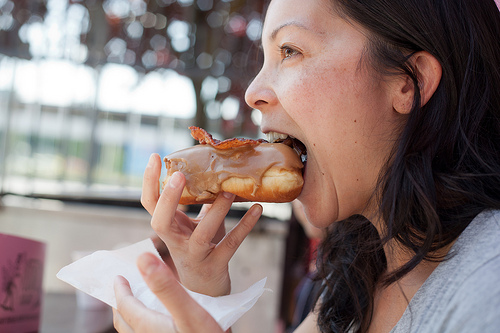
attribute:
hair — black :
[390, 75, 459, 225]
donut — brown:
[156, 106, 347, 286]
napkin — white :
[32, 218, 268, 328]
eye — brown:
[254, 24, 346, 78]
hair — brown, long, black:
[304, 0, 484, 330]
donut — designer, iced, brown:
[162, 121, 306, 204]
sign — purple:
[0, 230, 47, 330]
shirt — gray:
[388, 206, 485, 330]